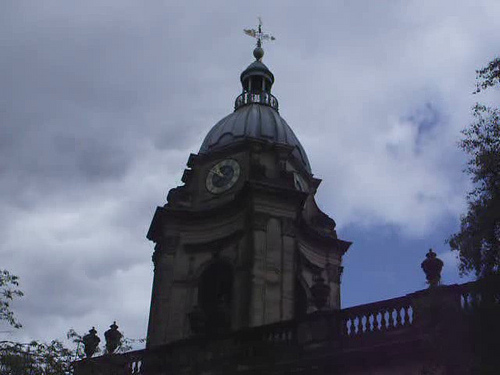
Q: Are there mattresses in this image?
A: No, there are no mattresses.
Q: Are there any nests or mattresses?
A: No, there are no mattresses or nests.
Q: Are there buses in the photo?
A: No, there are no buses.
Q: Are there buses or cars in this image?
A: No, there are no buses or cars.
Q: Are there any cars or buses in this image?
A: No, there are no buses or cars.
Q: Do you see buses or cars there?
A: No, there are no buses or cars.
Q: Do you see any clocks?
A: Yes, there is a clock.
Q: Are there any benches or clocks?
A: Yes, there is a clock.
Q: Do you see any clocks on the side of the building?
A: Yes, there is a clock on the side of the building.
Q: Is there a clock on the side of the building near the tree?
A: Yes, there is a clock on the side of the building.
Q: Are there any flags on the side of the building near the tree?
A: No, there is a clock on the side of the building.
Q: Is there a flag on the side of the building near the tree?
A: No, there is a clock on the side of the building.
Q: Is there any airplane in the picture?
A: No, there are no airplanes.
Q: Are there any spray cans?
A: No, there are no spray cans.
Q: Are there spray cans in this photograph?
A: No, there are no spray cans.